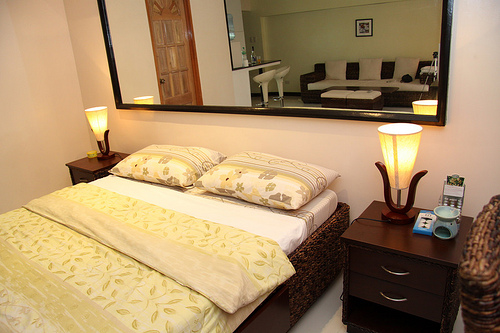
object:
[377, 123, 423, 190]
lamp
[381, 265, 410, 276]
handles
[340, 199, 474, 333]
drawers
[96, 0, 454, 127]
frame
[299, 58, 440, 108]
couch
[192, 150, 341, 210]
pillows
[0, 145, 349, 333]
bed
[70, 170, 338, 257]
bedspread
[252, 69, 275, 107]
chairs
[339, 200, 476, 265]
table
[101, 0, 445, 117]
mirror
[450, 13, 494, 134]
wall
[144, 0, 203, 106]
door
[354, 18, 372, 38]
photo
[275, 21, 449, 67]
wall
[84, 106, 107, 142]
lamp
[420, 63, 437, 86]
basket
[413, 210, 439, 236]
remote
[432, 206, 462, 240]
candle holder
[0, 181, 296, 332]
comforter